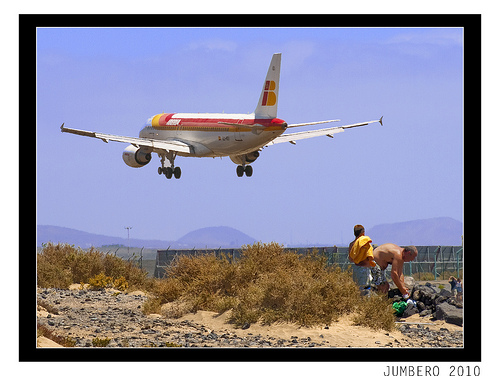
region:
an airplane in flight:
[57, 47, 394, 185]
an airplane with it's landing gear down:
[52, 51, 394, 184]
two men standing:
[341, 219, 415, 305]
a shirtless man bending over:
[372, 236, 417, 301]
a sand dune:
[141, 291, 463, 351]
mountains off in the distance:
[32, 216, 268, 246]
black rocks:
[409, 281, 468, 328]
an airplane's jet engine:
[115, 141, 157, 172]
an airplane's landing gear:
[229, 157, 257, 180]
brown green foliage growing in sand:
[142, 237, 399, 329]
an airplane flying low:
[53, 47, 397, 185]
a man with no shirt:
[371, 231, 436, 288]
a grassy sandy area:
[38, 235, 400, 347]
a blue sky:
[38, 28, 460, 247]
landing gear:
[157, 160, 263, 184]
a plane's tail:
[216, 45, 340, 137]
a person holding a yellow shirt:
[346, 215, 378, 303]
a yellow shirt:
[348, 235, 380, 267]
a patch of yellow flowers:
[78, 267, 131, 294]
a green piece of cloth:
[391, 297, 420, 316]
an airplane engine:
[111, 137, 166, 169]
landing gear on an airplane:
[151, 159, 213, 182]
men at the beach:
[327, 213, 437, 300]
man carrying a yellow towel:
[336, 225, 389, 290]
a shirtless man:
[368, 222, 424, 299]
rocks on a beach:
[87, 285, 134, 334]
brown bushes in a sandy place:
[175, 237, 347, 339]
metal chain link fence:
[123, 253, 153, 278]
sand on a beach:
[268, 305, 383, 345]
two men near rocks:
[315, 210, 447, 316]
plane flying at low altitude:
[52, 44, 399, 184]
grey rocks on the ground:
[125, 324, 215, 342]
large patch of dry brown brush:
[152, 245, 387, 325]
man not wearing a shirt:
[375, 236, 419, 293]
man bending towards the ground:
[379, 238, 421, 318]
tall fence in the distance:
[105, 241, 462, 282]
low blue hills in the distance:
[38, 215, 460, 243]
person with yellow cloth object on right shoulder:
[345, 222, 375, 269]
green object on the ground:
[390, 297, 409, 319]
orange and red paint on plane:
[145, 110, 290, 135]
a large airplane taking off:
[48, 47, 398, 192]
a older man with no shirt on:
[371, 232, 421, 298]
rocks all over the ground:
[43, 285, 463, 355]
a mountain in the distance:
[165, 216, 271, 247]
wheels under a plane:
[150, 140, 275, 182]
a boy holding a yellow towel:
[345, 217, 381, 290]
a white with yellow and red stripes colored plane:
[67, 83, 392, 174]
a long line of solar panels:
[143, 236, 458, 286]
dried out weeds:
[133, 243, 393, 329]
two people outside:
[336, 200, 433, 315]